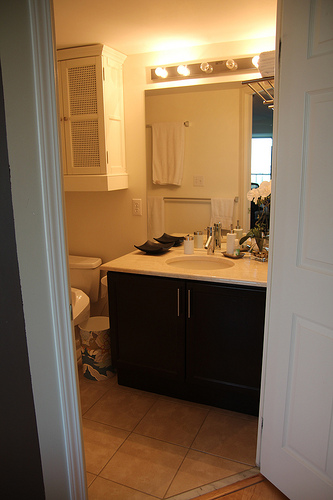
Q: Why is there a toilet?
A: It's a bathroom.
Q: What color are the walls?
A: White.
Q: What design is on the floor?
A: Square tile.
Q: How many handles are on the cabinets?
A: Two.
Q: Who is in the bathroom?
A: No one.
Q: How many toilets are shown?
A: One.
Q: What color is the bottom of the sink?
A: Black.